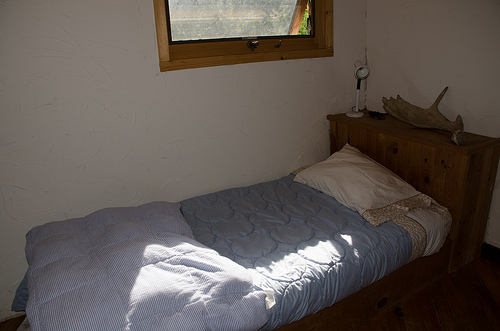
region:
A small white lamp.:
[344, 56, 369, 118]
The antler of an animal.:
[383, 85, 466, 145]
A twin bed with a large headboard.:
[13, 107, 498, 329]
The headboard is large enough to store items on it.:
[326, 106, 498, 267]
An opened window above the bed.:
[151, 0, 335, 72]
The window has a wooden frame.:
[152, 0, 334, 72]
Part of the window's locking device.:
[245, 38, 284, 52]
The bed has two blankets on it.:
[12, 142, 452, 329]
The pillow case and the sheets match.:
[291, 143, 451, 261]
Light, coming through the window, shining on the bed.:
[124, 233, 356, 330]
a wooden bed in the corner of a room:
[13, 108, 497, 330]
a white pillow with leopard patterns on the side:
[295, 141, 433, 223]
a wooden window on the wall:
[151, 2, 336, 71]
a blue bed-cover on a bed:
[180, 173, 415, 328]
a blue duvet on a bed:
[24, 199, 271, 329]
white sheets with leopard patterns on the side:
[397, 203, 450, 258]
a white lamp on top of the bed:
[348, 58, 370, 120]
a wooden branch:
[379, 84, 466, 144]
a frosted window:
[168, 0, 312, 40]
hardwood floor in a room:
[1, 247, 498, 329]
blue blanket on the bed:
[24, 175, 215, 320]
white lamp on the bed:
[349, 60, 369, 120]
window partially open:
[186, 13, 333, 56]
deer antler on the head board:
[373, 70, 475, 150]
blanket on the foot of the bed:
[15, 198, 230, 320]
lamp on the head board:
[341, 52, 371, 113]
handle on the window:
[242, 32, 263, 54]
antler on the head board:
[371, 70, 471, 158]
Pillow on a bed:
[297, 137, 433, 229]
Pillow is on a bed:
[294, 142, 435, 227]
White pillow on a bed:
[289, 139, 437, 227]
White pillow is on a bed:
[289, 135, 437, 230]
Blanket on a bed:
[14, 165, 426, 330]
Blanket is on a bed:
[10, 158, 435, 328]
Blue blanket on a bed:
[10, 158, 420, 329]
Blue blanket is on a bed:
[12, 163, 416, 329]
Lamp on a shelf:
[337, 51, 379, 122]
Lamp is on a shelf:
[341, 50, 375, 125]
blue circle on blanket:
[260, 188, 299, 205]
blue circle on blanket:
[286, 199, 317, 221]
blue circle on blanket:
[310, 210, 342, 233]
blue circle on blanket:
[332, 228, 374, 250]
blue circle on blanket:
[298, 235, 344, 263]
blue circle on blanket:
[270, 220, 315, 242]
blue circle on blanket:
[251, 208, 288, 229]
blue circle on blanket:
[228, 193, 270, 210]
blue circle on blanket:
[256, 250, 306, 285]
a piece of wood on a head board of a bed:
[376, 85, 471, 145]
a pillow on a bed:
[310, 143, 427, 235]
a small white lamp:
[346, 56, 367, 118]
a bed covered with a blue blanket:
[242, 167, 394, 328]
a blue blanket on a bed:
[15, 192, 266, 329]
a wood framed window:
[148, 5, 344, 70]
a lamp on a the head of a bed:
[337, 52, 374, 133]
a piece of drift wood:
[380, 81, 471, 142]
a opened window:
[227, 6, 327, 46]